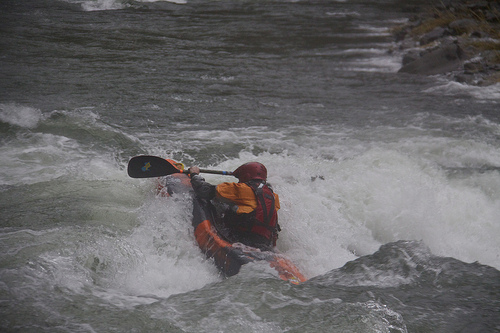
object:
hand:
[188, 166, 200, 175]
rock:
[406, 71, 457, 88]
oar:
[126, 155, 233, 178]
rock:
[425, 81, 498, 100]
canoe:
[125, 155, 306, 286]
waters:
[399, 160, 496, 240]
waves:
[417, 147, 497, 217]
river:
[296, 16, 383, 63]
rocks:
[387, 0, 426, 21]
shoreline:
[331, 0, 500, 107]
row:
[126, 155, 235, 178]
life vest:
[215, 182, 281, 215]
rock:
[396, 42, 421, 62]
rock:
[425, 67, 450, 87]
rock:
[424, 30, 446, 44]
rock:
[447, 16, 469, 34]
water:
[51, 191, 170, 244]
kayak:
[125, 155, 304, 288]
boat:
[126, 155, 304, 286]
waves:
[110, 258, 500, 333]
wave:
[9, 106, 484, 281]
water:
[315, 0, 398, 55]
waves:
[0, 96, 137, 192]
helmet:
[231, 162, 266, 183]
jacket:
[216, 182, 280, 215]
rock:
[51, 253, 499, 333]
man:
[188, 162, 281, 246]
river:
[42, 213, 137, 269]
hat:
[231, 162, 267, 183]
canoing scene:
[13, 11, 488, 325]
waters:
[348, 178, 459, 241]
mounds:
[429, 5, 499, 54]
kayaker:
[123, 130, 303, 284]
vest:
[215, 182, 280, 215]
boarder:
[188, 162, 282, 248]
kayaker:
[191, 158, 288, 273]